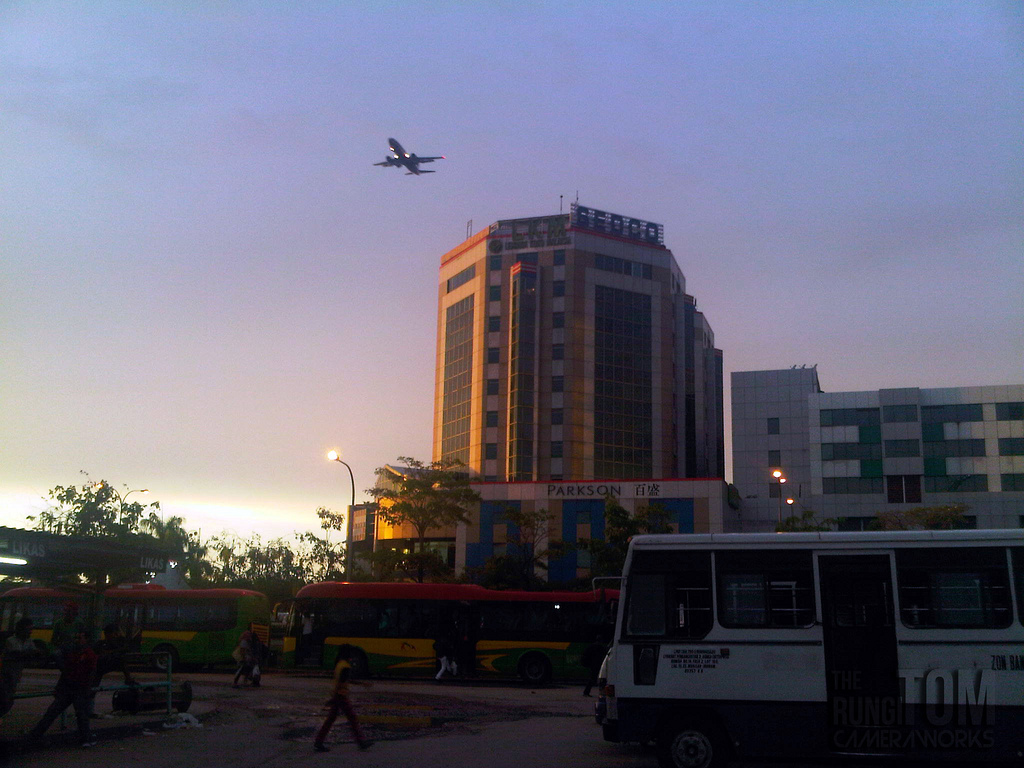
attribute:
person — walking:
[313, 646, 372, 751]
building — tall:
[433, 202, 721, 478]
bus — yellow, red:
[275, 580, 620, 688]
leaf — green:
[81, 485, 86, 490]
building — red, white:
[432, 219, 716, 490]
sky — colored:
[740, 111, 875, 285]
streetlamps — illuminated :
[281, 427, 393, 536]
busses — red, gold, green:
[44, 558, 612, 715]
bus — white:
[297, 561, 594, 696]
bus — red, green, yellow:
[64, 564, 325, 682]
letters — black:
[518, 167, 701, 282]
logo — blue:
[4, 520, 177, 572]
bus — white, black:
[585, 529, 1020, 758]